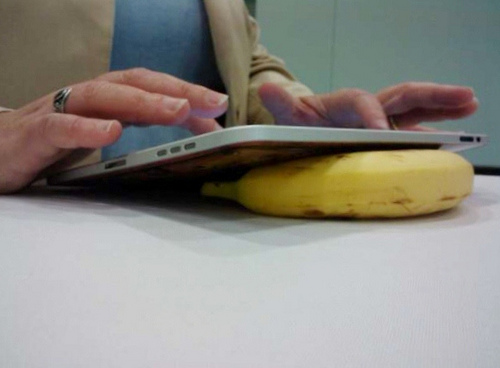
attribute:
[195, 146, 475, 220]
banana — yellow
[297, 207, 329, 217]
spot — brown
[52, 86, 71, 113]
ring — silver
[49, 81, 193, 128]
finger — small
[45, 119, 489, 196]
tablet — white, rectangle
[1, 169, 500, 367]
table — gray, white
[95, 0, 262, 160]
shirt — light blue, blue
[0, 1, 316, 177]
jacket — brown, beige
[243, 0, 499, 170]
wall — white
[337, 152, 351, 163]
spot — brown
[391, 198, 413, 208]
spot — brown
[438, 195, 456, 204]
spot — brown